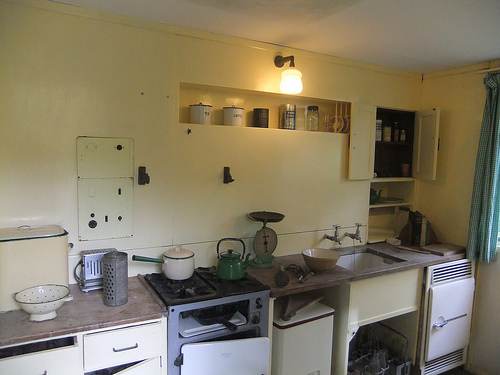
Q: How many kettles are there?
A: 1.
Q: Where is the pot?
A: On the stove.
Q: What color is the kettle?
A: Green.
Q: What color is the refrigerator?
A: White.